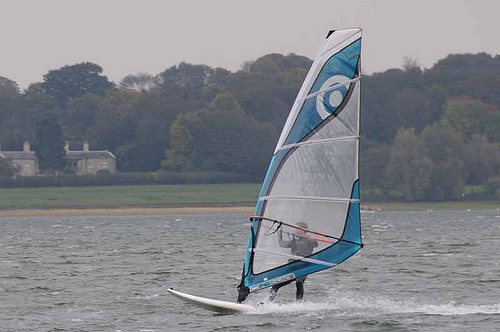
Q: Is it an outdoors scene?
A: Yes, it is outdoors.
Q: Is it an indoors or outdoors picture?
A: It is outdoors.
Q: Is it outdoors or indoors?
A: It is outdoors.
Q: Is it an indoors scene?
A: No, it is outdoors.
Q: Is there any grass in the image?
A: Yes, there is grass.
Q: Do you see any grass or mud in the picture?
A: Yes, there is grass.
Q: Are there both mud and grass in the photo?
A: No, there is grass but no mud.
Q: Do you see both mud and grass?
A: No, there is grass but no mud.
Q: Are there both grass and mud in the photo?
A: No, there is grass but no mud.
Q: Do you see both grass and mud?
A: No, there is grass but no mud.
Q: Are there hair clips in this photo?
A: No, there are no hair clips.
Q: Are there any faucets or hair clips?
A: No, there are no hair clips or faucets.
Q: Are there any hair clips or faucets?
A: No, there are no hair clips or faucets.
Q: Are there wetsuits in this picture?
A: Yes, there is a wetsuit.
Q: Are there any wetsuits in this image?
A: Yes, there is a wetsuit.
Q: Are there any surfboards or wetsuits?
A: Yes, there is a wetsuit.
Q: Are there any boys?
A: No, there are no boys.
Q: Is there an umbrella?
A: No, there are no umbrellas.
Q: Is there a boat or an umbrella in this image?
A: No, there are no umbrellas or boats.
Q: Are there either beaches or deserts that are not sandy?
A: No, there is a beach but it is sandy.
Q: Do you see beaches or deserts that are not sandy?
A: No, there is a beach but it is sandy.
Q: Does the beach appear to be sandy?
A: Yes, the beach is sandy.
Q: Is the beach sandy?
A: Yes, the beach is sandy.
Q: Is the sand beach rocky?
A: No, the beach is sandy.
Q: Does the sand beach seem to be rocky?
A: No, the beach is sandy.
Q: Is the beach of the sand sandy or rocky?
A: The beach is sandy.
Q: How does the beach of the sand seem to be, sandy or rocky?
A: The beach is sandy.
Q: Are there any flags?
A: No, there are no flags.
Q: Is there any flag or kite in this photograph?
A: No, there are no flags or kites.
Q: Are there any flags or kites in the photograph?
A: No, there are no flags or kites.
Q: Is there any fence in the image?
A: No, there are no fences.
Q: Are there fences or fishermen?
A: No, there are no fences or fishermen.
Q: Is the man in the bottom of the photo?
A: Yes, the man is in the bottom of the image.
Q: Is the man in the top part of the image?
A: No, the man is in the bottom of the image.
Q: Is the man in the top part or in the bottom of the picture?
A: The man is in the bottom of the image.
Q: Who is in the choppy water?
A: The man is in the water.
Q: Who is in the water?
A: The man is in the water.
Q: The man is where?
A: The man is in the water.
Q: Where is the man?
A: The man is in the water.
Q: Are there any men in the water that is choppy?
A: Yes, there is a man in the water.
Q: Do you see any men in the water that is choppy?
A: Yes, there is a man in the water.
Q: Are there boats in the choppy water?
A: No, there is a man in the water.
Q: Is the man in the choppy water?
A: Yes, the man is in the water.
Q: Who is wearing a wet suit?
A: The man is wearing a wet suit.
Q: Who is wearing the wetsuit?
A: The man is wearing a wet suit.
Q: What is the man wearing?
A: The man is wearing a wetsuit.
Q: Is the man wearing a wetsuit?
A: Yes, the man is wearing a wetsuit.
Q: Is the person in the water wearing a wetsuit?
A: Yes, the man is wearing a wetsuit.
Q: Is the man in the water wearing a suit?
A: No, the man is wearing a wetsuit.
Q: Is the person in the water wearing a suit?
A: No, the man is wearing a wetsuit.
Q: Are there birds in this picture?
A: No, there are no birds.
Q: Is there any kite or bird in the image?
A: No, there are no birds or kites.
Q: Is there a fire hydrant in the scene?
A: No, there are no fire hydrants.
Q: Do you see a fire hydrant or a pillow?
A: No, there are no fire hydrants or pillows.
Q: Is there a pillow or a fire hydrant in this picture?
A: No, there are no fire hydrants or pillows.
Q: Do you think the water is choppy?
A: Yes, the water is choppy.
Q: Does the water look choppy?
A: Yes, the water is choppy.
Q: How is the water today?
A: The water is choppy.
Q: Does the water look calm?
A: No, the water is choppy.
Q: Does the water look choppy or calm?
A: The water is choppy.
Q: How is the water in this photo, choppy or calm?
A: The water is choppy.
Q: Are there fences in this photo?
A: No, there are no fences.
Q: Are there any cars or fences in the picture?
A: No, there are no fences or cars.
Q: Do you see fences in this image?
A: No, there are no fences.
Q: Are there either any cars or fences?
A: No, there are no fences or cars.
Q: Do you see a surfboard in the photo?
A: Yes, there is a surfboard.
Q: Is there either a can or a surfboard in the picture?
A: Yes, there is a surfboard.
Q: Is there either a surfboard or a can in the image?
A: Yes, there is a surfboard.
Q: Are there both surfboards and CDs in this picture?
A: No, there is a surfboard but no cds.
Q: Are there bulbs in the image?
A: No, there are no bulbs.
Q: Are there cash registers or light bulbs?
A: No, there are no light bulbs or cash registers.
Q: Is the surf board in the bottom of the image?
A: Yes, the surf board is in the bottom of the image.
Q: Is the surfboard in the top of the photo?
A: No, the surfboard is in the bottom of the image.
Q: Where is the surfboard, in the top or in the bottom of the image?
A: The surfboard is in the bottom of the image.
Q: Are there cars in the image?
A: No, there are no cars.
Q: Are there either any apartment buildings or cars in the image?
A: No, there are no cars or apartment buildings.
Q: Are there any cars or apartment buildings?
A: No, there are no cars or apartment buildings.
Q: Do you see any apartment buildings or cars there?
A: No, there are no cars or apartment buildings.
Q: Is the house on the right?
A: No, the house is on the left of the image.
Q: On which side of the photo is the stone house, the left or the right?
A: The house is on the left of the image.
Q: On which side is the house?
A: The house is on the left of the image.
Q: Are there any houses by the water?
A: Yes, there is a house by the water.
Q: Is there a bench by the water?
A: No, there is a house by the water.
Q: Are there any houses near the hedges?
A: Yes, there is a house near the hedges.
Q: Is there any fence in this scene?
A: No, there are no fences.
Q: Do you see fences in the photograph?
A: No, there are no fences.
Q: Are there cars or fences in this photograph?
A: No, there are no fences or cars.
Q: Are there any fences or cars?
A: No, there are no fences or cars.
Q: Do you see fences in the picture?
A: No, there are no fences.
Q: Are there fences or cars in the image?
A: No, there are no fences or cars.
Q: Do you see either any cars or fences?
A: No, there are no fences or cars.